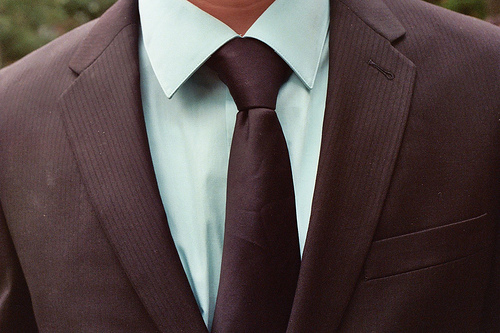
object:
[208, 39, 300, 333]
tie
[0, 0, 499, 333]
coat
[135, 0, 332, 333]
shirt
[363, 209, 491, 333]
pocket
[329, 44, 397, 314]
stripe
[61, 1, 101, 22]
bench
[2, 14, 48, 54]
tree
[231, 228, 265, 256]
wrinkle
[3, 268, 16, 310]
wrinkle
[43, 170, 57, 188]
spot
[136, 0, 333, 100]
collar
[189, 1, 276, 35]
neck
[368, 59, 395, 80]
button hole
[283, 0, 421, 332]
lapel